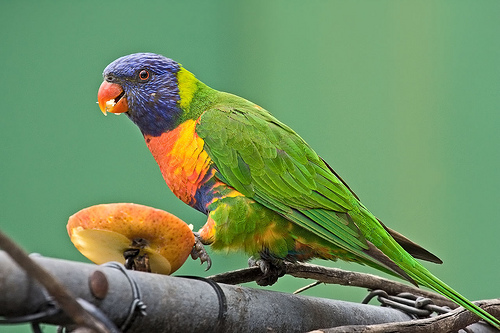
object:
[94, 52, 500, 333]
bird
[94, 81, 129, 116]
beak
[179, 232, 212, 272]
claw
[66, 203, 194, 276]
potato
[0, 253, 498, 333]
branch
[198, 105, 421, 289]
wings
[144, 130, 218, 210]
chest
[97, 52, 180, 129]
face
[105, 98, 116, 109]
food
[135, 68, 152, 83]
eye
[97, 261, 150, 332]
wire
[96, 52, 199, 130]
head